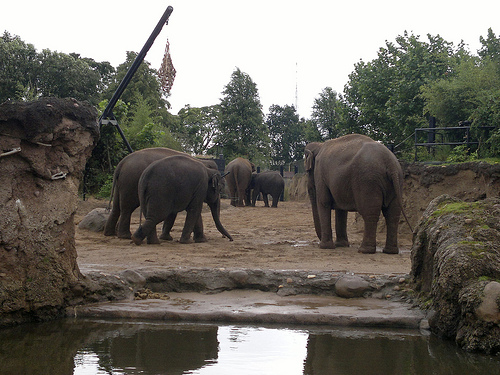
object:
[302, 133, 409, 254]
elephant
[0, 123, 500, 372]
pen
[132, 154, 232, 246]
elephants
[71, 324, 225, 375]
reflection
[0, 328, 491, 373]
water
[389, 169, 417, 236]
tail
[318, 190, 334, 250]
feet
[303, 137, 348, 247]
front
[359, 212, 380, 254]
feet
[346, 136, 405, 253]
back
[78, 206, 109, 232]
stone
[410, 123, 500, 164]
fence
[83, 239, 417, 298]
mud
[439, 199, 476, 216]
grass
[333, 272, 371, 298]
rock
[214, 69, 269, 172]
tree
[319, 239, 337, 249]
foot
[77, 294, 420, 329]
step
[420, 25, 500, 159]
trees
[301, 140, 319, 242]
head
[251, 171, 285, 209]
elephant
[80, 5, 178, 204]
pole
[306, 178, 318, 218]
tusk